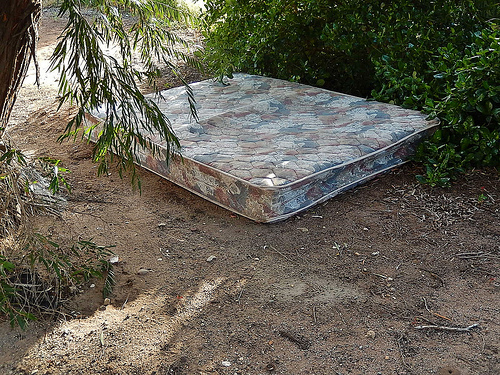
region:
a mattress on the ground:
[72, 53, 439, 264]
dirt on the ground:
[384, 167, 461, 370]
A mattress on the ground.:
[82, 53, 427, 212]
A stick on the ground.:
[401, 283, 485, 341]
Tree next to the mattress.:
[291, 28, 469, 110]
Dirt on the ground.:
[107, 224, 263, 319]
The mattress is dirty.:
[171, 71, 333, 181]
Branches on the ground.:
[25, 247, 77, 327]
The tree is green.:
[319, 19, 467, 86]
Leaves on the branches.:
[51, 23, 193, 179]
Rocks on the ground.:
[97, 227, 212, 294]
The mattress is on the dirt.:
[158, 75, 368, 216]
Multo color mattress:
[175, 93, 333, 188]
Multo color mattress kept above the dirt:
[164, 80, 389, 277]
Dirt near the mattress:
[196, 258, 391, 349]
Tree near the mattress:
[6, 10, 126, 112]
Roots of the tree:
[23, 158, 61, 208]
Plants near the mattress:
[380, 13, 466, 78]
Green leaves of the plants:
[431, 12, 475, 82]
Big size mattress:
[173, 88, 375, 173]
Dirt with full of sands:
[107, 234, 397, 348]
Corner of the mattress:
[243, 173, 302, 230]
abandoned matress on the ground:
[82, 72, 440, 225]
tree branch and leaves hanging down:
[48, 4, 223, 192]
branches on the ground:
[0, 152, 117, 327]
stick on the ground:
[415, 321, 479, 336]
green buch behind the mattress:
[201, 4, 499, 182]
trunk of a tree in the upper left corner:
[0, 0, 39, 146]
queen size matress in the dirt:
[84, 71, 441, 226]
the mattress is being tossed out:
[86, 75, 440, 228]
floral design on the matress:
[82, 71, 439, 221]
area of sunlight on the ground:
[25, 31, 208, 83]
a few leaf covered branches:
[39, 0, 219, 174]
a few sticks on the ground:
[406, 295, 481, 338]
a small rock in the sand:
[133, 266, 152, 278]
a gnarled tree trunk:
[7, 0, 44, 147]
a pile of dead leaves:
[397, 181, 472, 233]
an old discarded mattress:
[78, 70, 445, 225]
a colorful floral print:
[226, 90, 371, 157]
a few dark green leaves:
[415, 41, 497, 161]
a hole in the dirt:
[0, 268, 65, 338]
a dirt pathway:
[28, 18, 460, 358]